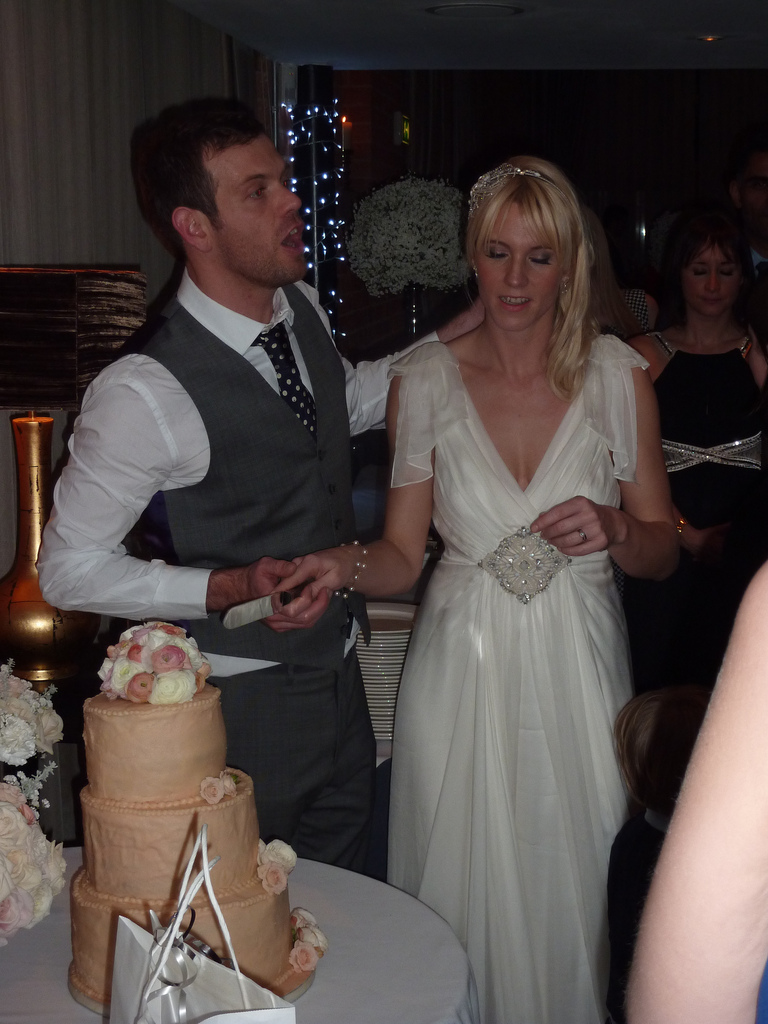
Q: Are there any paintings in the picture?
A: No, there are no paintings.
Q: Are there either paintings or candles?
A: No, there are no paintings or candles.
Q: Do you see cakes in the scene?
A: Yes, there is a cake.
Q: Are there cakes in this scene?
A: Yes, there is a cake.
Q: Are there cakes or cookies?
A: Yes, there is a cake.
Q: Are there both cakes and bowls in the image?
A: No, there is a cake but no bowls.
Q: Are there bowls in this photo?
A: No, there are no bowls.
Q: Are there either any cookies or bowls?
A: No, there are no bowls or cookies.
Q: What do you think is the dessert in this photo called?
A: The dessert is a cake.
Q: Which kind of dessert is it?
A: The dessert is a cake.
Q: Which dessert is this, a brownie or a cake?
A: That is a cake.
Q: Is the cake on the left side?
A: Yes, the cake is on the left of the image.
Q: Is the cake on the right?
A: No, the cake is on the left of the image.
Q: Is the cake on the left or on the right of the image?
A: The cake is on the left of the image.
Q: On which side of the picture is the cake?
A: The cake is on the left of the image.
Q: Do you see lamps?
A: Yes, there is a lamp.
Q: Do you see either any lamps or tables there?
A: Yes, there is a lamp.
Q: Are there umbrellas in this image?
A: No, there are no umbrellas.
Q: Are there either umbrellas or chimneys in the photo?
A: No, there are no umbrellas or chimneys.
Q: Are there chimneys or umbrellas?
A: No, there are no umbrellas or chimneys.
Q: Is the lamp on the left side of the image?
A: Yes, the lamp is on the left of the image.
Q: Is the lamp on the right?
A: No, the lamp is on the left of the image.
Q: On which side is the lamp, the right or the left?
A: The lamp is on the left of the image.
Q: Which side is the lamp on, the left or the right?
A: The lamp is on the left of the image.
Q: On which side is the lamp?
A: The lamp is on the left of the image.